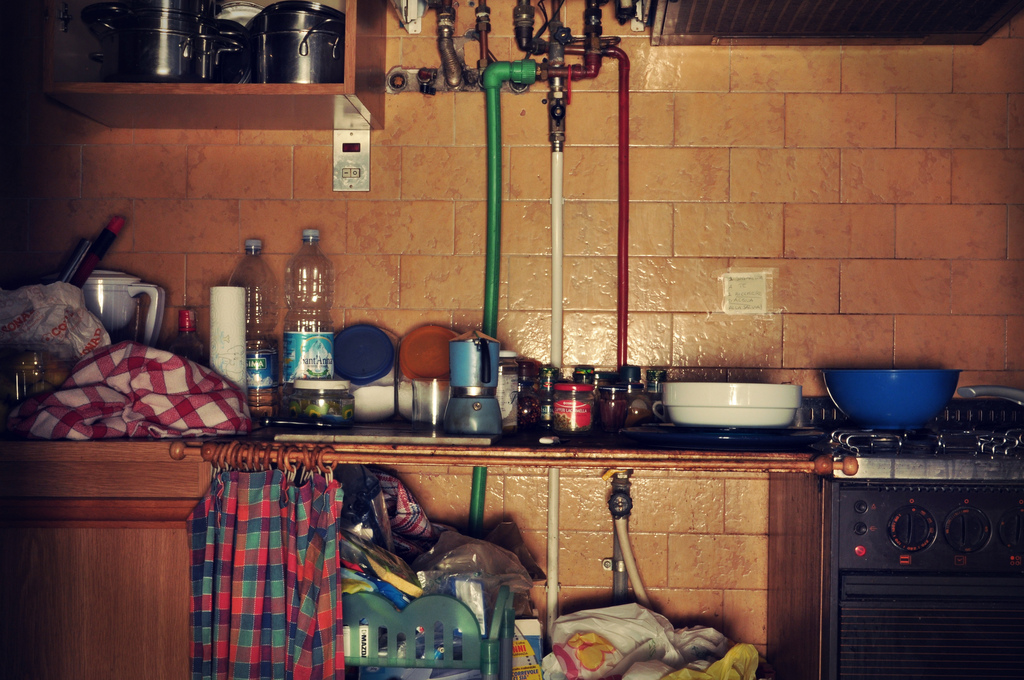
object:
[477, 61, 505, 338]
green pipe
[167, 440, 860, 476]
pole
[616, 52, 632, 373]
supply pipe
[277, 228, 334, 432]
oil bottle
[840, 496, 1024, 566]
knobs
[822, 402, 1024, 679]
cooking range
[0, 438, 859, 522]
countertop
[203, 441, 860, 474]
counter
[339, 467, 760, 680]
stuff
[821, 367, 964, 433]
serving bowl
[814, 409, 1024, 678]
stove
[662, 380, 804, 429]
bowl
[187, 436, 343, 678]
curtain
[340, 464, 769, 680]
compartment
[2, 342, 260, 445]
cloth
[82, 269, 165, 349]
blender container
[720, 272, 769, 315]
paper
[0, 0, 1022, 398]
wall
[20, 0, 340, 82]
pans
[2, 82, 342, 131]
shelf